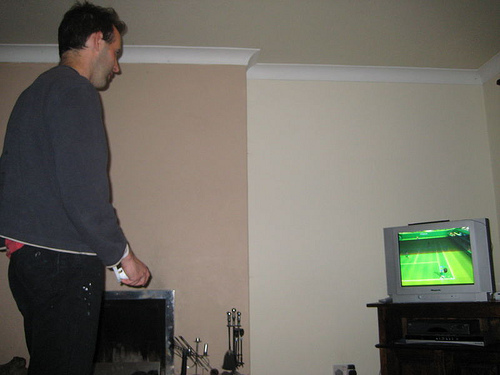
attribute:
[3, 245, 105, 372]
pants — black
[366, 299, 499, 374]
entertainment center — small, wooden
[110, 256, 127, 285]
controller — white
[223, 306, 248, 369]
fireplace pokers — set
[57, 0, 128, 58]
hair — dark, human